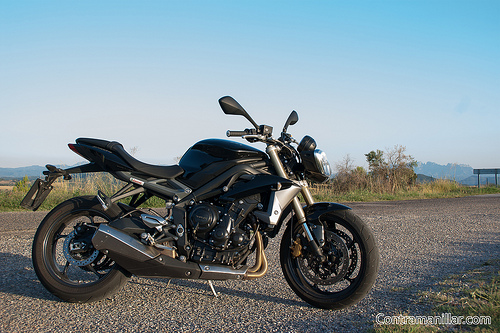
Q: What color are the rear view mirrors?
A: Black.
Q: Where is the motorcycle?
A: On a dirt road.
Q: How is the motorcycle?
A: Parked.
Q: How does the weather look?
A: Clear.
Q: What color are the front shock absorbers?
A: Silver.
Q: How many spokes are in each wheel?
A: 5.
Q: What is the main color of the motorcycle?
A: Black.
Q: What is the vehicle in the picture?
A: A motorcycle.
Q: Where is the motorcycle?
A: On the road.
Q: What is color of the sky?
A: Blue.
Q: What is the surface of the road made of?
A: Gravel.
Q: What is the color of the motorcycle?
A: Black.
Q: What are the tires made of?
A: Rubber.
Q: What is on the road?
A: A motorcycle.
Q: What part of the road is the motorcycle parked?
A: The middle.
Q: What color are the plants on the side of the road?
A: Green.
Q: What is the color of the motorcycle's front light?
A: Silver.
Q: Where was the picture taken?
A: On a road.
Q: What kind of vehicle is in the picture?
A: A motorcycle.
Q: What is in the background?
A: Sky.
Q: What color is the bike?
A: Black.